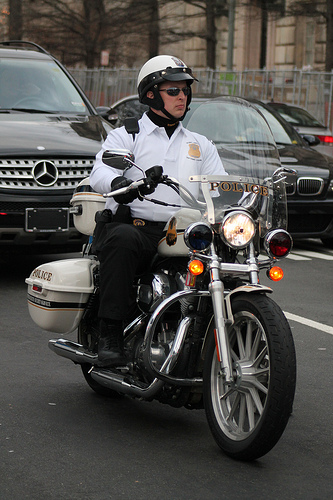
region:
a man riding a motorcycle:
[89, 69, 273, 491]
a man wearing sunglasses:
[143, 59, 205, 126]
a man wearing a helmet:
[125, 56, 197, 119]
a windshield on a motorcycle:
[179, 97, 296, 248]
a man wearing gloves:
[104, 110, 184, 207]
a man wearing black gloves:
[101, 145, 183, 205]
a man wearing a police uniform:
[91, 57, 233, 270]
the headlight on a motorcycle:
[202, 194, 277, 258]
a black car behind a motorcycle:
[0, 69, 158, 296]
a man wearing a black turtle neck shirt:
[83, 77, 229, 146]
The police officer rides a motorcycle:
[71, 78, 306, 470]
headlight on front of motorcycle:
[175, 224, 301, 267]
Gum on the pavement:
[37, 390, 84, 435]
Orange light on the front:
[186, 255, 214, 280]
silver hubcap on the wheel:
[200, 325, 285, 422]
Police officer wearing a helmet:
[140, 48, 208, 138]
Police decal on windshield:
[205, 158, 277, 220]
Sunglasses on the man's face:
[156, 84, 194, 101]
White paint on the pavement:
[289, 299, 328, 332]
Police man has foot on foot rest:
[32, 318, 151, 381]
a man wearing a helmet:
[134, 45, 213, 140]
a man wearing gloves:
[83, 89, 205, 245]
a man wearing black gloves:
[67, 115, 178, 239]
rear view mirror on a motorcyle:
[90, 138, 151, 195]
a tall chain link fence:
[200, 58, 328, 98]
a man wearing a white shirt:
[140, 73, 197, 160]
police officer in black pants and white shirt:
[98, 47, 234, 351]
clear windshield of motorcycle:
[182, 91, 287, 267]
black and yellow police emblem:
[206, 181, 288, 191]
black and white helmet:
[127, 39, 197, 116]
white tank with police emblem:
[16, 255, 95, 349]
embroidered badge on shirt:
[180, 135, 215, 181]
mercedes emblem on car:
[23, 134, 88, 203]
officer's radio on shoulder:
[113, 108, 141, 164]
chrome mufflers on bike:
[41, 326, 175, 399]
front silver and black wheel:
[214, 279, 299, 457]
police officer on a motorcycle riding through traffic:
[26, 52, 296, 462]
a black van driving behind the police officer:
[0, 38, 99, 186]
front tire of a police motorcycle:
[202, 290, 296, 462]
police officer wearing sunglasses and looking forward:
[90, 54, 220, 366]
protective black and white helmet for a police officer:
[137, 55, 198, 86]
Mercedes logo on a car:
[28, 159, 59, 186]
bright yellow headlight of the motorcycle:
[218, 209, 257, 248]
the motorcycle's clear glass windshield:
[179, 95, 288, 215]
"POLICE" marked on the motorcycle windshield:
[206, 178, 268, 198]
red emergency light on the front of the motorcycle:
[263, 227, 292, 261]